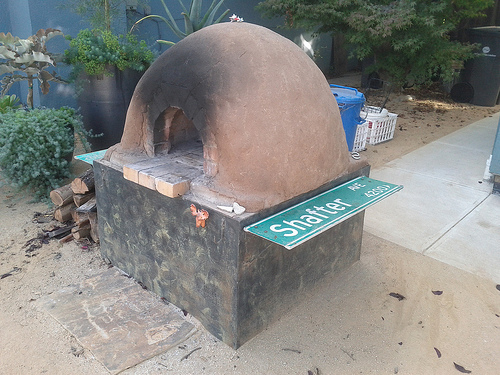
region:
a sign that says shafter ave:
[255, 169, 422, 256]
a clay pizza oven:
[106, 13, 344, 240]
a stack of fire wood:
[46, 152, 110, 239]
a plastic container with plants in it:
[69, 13, 158, 172]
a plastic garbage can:
[451, 17, 494, 109]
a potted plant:
[3, 86, 71, 194]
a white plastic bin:
[357, 95, 399, 154]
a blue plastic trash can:
[326, 70, 367, 162]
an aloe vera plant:
[149, 0, 239, 56]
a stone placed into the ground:
[35, 258, 195, 367]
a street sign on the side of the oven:
[246, 175, 416, 273]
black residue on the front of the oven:
[98, 36, 228, 173]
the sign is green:
[243, 162, 405, 279]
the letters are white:
[269, 194, 363, 237]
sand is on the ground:
[270, 251, 487, 371]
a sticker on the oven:
[174, 192, 229, 246]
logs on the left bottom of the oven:
[31, 162, 104, 251]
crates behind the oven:
[347, 100, 403, 154]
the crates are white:
[330, 92, 422, 159]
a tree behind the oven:
[277, 2, 467, 103]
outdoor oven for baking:
[86, 28, 351, 205]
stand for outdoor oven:
[91, 139, 352, 336]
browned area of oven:
[151, 58, 216, 100]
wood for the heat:
[45, 173, 98, 231]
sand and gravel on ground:
[20, 240, 166, 347]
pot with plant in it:
[70, 20, 140, 145]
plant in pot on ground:
[3, 105, 78, 181]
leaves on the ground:
[423, 339, 473, 374]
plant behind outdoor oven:
[142, 3, 231, 32]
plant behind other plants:
[1, 22, 61, 107]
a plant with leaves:
[17, 106, 89, 213]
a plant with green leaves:
[9, 72, 76, 188]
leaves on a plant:
[28, 103, 103, 225]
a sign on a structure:
[237, 164, 410, 259]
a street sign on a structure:
[240, 156, 350, 245]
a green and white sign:
[236, 164, 428, 259]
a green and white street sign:
[237, 175, 393, 265]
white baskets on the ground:
[347, 61, 447, 225]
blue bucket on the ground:
[324, 72, 369, 193]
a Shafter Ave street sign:
[240, 173, 406, 250]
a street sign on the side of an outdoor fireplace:
[240, 173, 405, 251]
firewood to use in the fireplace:
[47, 168, 95, 245]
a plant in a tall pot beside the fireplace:
[56, 28, 159, 146]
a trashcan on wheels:
[449, 23, 498, 108]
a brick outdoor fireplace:
[100, 20, 350, 215]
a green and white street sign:
[242, 175, 404, 252]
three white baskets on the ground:
[355, 104, 399, 152]